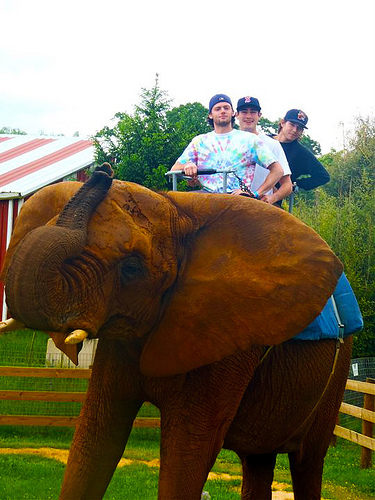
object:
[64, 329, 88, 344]
elephant tusk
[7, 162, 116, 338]
trunk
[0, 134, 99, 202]
tent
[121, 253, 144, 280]
eye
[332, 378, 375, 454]
fence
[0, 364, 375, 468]
fence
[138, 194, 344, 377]
ear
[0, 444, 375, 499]
dirt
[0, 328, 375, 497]
grass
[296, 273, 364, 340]
pad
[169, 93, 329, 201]
guy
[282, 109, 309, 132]
hat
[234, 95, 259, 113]
hat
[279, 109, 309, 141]
head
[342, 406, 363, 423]
ground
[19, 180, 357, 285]
wooden enclosure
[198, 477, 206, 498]
rock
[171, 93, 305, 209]
boy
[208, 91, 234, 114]
blue cap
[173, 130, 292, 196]
t-shirt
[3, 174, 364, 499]
elephant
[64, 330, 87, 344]
horn